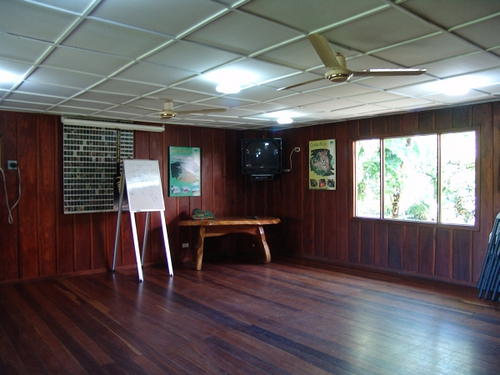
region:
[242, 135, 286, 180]
The black television mounted on the wall.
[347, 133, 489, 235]
The windows in th eroom.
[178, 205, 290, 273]
The wooden table below the mounted television.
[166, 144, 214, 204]
The art frame hanging on the wall above the wooden table.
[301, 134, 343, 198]
The poster on the wall next to the window.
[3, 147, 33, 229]
The wire plugged into the socket on the left.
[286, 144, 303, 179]
The wire attached to the television that is mounted on the wall.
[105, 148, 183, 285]
The art easel next to the wooden table.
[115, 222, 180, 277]
The legs of the art easel next to the wooden table.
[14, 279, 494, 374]
The wooden floor in the room.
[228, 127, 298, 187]
a television on the wall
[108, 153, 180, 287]
a white drawing board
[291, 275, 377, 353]
dark hard wood floors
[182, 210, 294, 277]
a wooden table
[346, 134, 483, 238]
3 pane window pane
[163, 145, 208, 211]
poster on the wall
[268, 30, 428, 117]
ceiling fan hanging from ceiling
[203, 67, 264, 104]
ceiling light fixture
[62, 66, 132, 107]
ceiling tile on roof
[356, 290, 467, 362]
sunlight reflection on wooden floor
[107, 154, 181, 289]
a white board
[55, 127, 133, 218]
a picture on the wall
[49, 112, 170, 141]
a white projector wall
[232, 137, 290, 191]
a tv on the wall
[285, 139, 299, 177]
a wire to the tv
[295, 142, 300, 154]
a plug in the socket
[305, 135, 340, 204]
a yellow picture on the wall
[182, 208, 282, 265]
a table under the tv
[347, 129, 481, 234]
a window on the wall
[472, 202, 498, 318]
a stack of folding chairs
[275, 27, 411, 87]
white ceiling fan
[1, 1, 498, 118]
white ceiling with square design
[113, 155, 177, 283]
white easel with dry erase board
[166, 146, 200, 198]
painting hanging on the wall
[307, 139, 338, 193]
painting hanging on the wall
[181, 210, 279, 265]
wooden table in the corner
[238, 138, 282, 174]
black television on wall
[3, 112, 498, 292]
wood paneling on wall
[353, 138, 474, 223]
window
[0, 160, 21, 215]
outlet with wire connected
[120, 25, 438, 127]
Two off-white ceiling fans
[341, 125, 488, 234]
Window to the outdoor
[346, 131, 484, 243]
Trees behind window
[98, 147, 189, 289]
Stand up white board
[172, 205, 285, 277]
Thick wooden table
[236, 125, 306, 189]
Mounted tube televison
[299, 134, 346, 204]
Framed picture on wood wall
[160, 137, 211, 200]
Picture with black frame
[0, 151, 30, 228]
Wire going in to electric outlet on wood wall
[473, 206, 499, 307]
Fold up chairs leaning against wooden wall